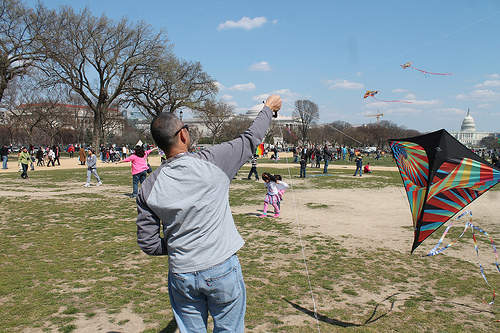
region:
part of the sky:
[277, 70, 291, 110]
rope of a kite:
[294, 240, 309, 265]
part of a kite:
[448, 187, 460, 202]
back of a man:
[184, 182, 196, 208]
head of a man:
[178, 123, 179, 125]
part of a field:
[45, 173, 68, 238]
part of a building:
[86, 100, 91, 106]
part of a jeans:
[228, 296, 232, 304]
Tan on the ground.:
[344, 190, 393, 228]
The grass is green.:
[16, 243, 68, 301]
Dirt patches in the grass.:
[63, 285, 147, 330]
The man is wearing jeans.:
[170, 270, 250, 330]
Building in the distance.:
[17, 98, 135, 149]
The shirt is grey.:
[128, 163, 235, 268]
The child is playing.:
[248, 159, 291, 229]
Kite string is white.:
[260, 117, 342, 315]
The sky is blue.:
[288, 9, 375, 74]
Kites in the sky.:
[331, 60, 473, 131]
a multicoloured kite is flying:
[385, 122, 491, 264]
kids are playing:
[224, 164, 296, 240]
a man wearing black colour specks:
[145, 107, 205, 163]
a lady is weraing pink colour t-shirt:
[126, 142, 149, 195]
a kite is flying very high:
[356, 80, 444, 111]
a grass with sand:
[22, 202, 128, 312]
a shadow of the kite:
[286, 285, 435, 329]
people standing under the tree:
[28, 55, 207, 167]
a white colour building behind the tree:
[449, 101, 489, 138]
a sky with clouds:
[248, 69, 358, 94]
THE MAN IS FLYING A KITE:
[121, 88, 279, 330]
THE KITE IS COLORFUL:
[380, 117, 499, 241]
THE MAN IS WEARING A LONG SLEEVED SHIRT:
[141, 102, 271, 263]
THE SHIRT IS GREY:
[128, 99, 282, 287]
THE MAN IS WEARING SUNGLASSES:
[172, 119, 192, 143]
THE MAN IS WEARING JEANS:
[162, 251, 257, 331]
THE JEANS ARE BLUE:
[157, 251, 245, 331]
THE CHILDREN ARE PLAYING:
[254, 162, 293, 221]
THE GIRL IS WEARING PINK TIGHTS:
[258, 197, 285, 217]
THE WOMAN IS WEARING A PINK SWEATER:
[115, 134, 152, 174]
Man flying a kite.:
[111, 76, 496, 331]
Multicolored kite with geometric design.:
[365, 117, 497, 264]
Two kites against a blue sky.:
[348, 55, 468, 115]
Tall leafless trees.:
[16, 20, 168, 117]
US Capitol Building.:
[402, 97, 495, 151]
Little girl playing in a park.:
[252, 164, 304, 231]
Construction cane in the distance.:
[351, 105, 392, 132]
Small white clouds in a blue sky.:
[198, 1, 358, 93]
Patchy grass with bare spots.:
[27, 227, 139, 297]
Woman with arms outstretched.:
[111, 129, 155, 197]